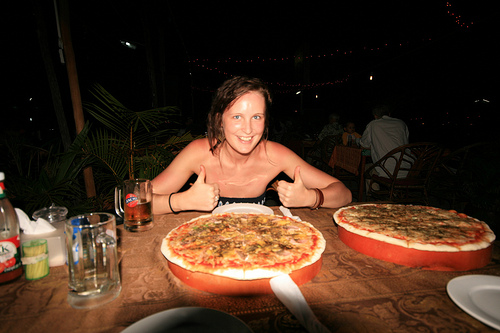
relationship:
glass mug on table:
[112, 176, 154, 232] [177, 190, 437, 270]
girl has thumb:
[135, 75, 352, 215] [196, 165, 205, 184]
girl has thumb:
[135, 75, 352, 215] [293, 166, 302, 181]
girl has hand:
[135, 75, 352, 215] [186, 164, 221, 212]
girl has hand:
[135, 75, 352, 215] [276, 165, 308, 207]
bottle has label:
[0, 172, 24, 286] [0, 230, 24, 272]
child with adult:
[339, 115, 365, 153] [354, 103, 419, 193]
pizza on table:
[160, 211, 325, 279] [1, 204, 499, 331]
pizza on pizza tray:
[339, 202, 499, 242] [338, 232, 497, 269]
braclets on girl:
[309, 188, 325, 211] [135, 75, 352, 210]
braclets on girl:
[308, 184, 325, 210] [135, 75, 352, 215]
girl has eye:
[135, 75, 352, 215] [248, 111, 261, 122]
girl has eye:
[135, 75, 352, 215] [228, 111, 243, 122]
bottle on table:
[0, 169, 27, 286] [1, 204, 499, 331]